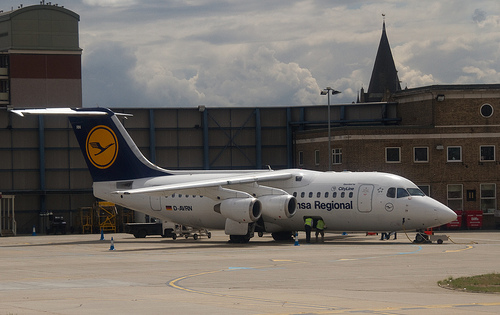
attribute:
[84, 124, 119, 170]
logo — yellow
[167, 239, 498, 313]
lines — yellow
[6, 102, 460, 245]
plane — parked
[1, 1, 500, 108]
sky — cloudy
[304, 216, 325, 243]
workers — working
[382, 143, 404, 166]
window — square